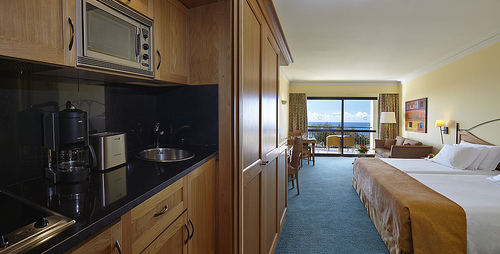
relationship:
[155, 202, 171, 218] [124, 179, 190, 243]
handle of drawer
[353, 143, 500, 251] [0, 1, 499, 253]
bed in room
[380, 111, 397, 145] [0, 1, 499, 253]
lamp in room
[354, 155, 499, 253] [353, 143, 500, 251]
blanket on beds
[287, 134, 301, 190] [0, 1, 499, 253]
chair in room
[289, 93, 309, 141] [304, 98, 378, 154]
curtains on window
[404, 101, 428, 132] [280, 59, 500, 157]
picture on wall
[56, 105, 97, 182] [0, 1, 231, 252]
coffee maker in kitchen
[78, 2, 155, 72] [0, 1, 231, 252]
microwave in kitchen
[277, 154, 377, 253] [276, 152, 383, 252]
carpet on floor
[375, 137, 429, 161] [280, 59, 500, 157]
sofa against wall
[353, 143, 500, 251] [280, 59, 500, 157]
beds against wall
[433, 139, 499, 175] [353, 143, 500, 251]
pillows on beds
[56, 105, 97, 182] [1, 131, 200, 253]
coffee maker on counter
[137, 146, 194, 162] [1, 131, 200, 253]
sink on counter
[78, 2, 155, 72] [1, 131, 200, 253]
microwave on counter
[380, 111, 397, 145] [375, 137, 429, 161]
lamp next to sofa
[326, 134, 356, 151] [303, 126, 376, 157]
bench on balcony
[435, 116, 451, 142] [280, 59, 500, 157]
wall lamp on wall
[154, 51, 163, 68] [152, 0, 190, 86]
handle on cabinet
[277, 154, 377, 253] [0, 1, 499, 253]
carpet in room